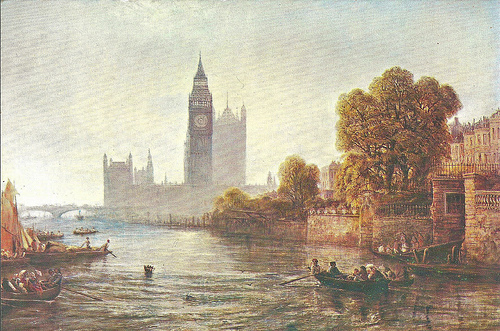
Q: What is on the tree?
A: Green leaves.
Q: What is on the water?
A: Row boats.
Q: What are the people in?
A: Boat.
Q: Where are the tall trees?
A: On the right.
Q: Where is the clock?
A: On the building.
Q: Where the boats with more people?
A: On left.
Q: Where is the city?
A: Straight ahead.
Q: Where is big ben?
A: Straight forward.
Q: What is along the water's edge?
A: Trees.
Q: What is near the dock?
A: A boat.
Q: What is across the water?
A: Big Ben.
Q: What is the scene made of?
A: Paint.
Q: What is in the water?
A: Boat.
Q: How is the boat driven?
A: Paddled.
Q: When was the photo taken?
A: Daytime.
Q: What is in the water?
A: Boats.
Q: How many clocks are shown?
A: One.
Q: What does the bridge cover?
A: Water.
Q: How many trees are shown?
A: Three.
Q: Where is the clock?
A: Tower.